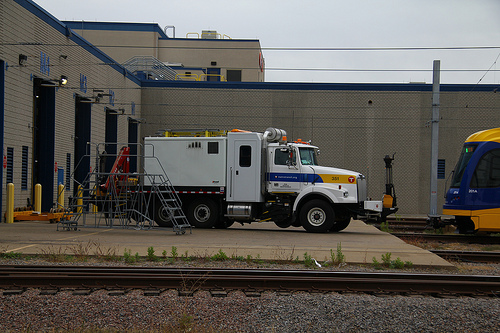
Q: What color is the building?
A: Grey-brown and blue.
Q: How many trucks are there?
A: One.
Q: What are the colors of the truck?
A: White, blue, and yellow.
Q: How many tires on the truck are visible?
A: Five.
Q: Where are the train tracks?
A: In front of and to the side of the building.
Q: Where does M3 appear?
A: Above the second loading dock door.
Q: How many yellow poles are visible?
A: Five.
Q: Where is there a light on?
A: Above the M4 loading dock door.